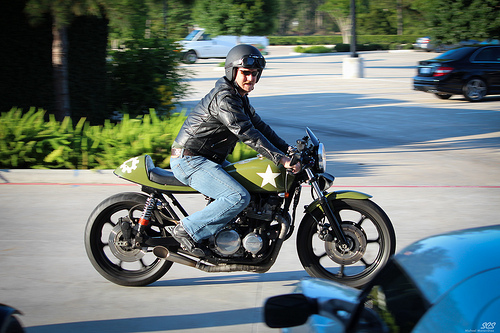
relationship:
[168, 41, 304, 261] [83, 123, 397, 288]
man riding motorcycle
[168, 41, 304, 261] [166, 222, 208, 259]
man wearing shoe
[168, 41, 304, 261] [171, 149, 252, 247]
man wearing jeans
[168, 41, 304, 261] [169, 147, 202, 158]
man wearing belt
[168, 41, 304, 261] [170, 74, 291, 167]
man wearing jacket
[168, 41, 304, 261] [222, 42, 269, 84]
man wearing helmet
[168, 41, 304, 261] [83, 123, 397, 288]
man on top of motorcycle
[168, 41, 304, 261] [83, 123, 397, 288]
man sitting on motorcycle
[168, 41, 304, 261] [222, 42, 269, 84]
man has helmet